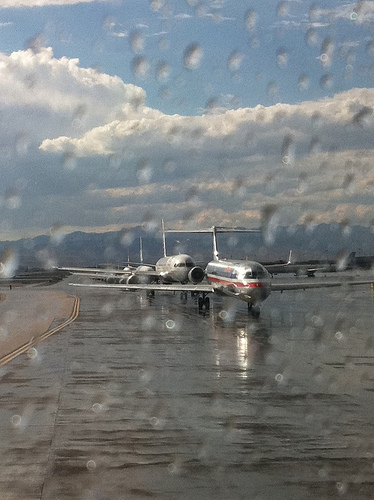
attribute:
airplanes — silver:
[47, 217, 370, 322]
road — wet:
[7, 266, 374, 498]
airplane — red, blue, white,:
[68, 218, 369, 332]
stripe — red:
[205, 272, 265, 293]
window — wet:
[246, 271, 268, 281]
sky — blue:
[1, 1, 374, 235]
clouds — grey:
[2, 45, 372, 163]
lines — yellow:
[1, 290, 83, 367]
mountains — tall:
[2, 224, 373, 262]